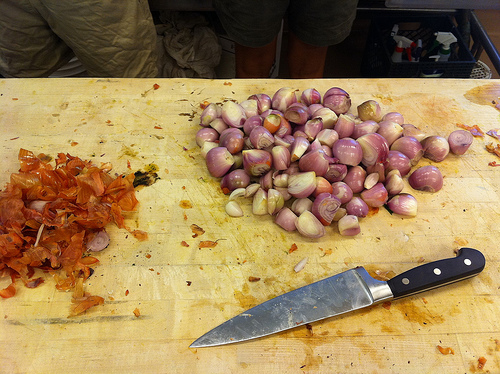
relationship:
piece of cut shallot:
[212, 142, 243, 188] [206, 148, 234, 178]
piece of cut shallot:
[212, 142, 243, 188] [406, 160, 446, 191]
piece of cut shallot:
[212, 142, 243, 188] [243, 145, 273, 177]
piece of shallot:
[284, 102, 310, 129] [268, 110, 302, 138]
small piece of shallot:
[145, 219, 219, 279] [273, 82, 295, 104]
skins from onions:
[1, 146, 150, 318] [200, 79, 471, 246]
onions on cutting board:
[200, 79, 471, 246] [0, 70, 497, 370]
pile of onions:
[192, 78, 479, 238] [195, 78, 487, 240]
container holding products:
[356, 11, 477, 79] [388, 23, 400, 38]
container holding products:
[356, 11, 477, 79] [388, 32, 418, 63]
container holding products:
[356, 11, 477, 79] [407, 35, 428, 62]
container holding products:
[356, 11, 477, 79] [433, 29, 456, 66]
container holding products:
[356, 11, 477, 79] [423, 50, 445, 83]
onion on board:
[329, 144, 459, 218] [6, 72, 498, 367]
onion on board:
[330, 134, 364, 169] [6, 72, 498, 367]